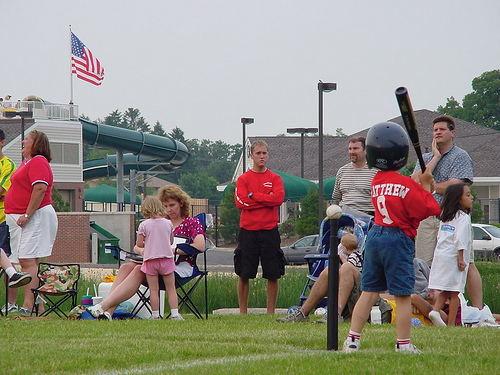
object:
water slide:
[80, 119, 189, 179]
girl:
[135, 195, 186, 320]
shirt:
[135, 217, 176, 261]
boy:
[232, 139, 286, 317]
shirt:
[232, 169, 286, 230]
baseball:
[325, 202, 342, 221]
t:
[327, 218, 340, 352]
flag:
[68, 30, 106, 87]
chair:
[32, 259, 82, 316]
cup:
[78, 295, 91, 319]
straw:
[85, 284, 90, 295]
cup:
[91, 294, 102, 306]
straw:
[92, 281, 98, 295]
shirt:
[370, 168, 442, 239]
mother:
[85, 182, 209, 318]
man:
[234, 137, 286, 318]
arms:
[234, 174, 264, 210]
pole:
[316, 89, 324, 228]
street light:
[315, 80, 340, 94]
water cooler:
[77, 278, 167, 321]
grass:
[1, 312, 499, 374]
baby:
[335, 232, 365, 274]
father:
[273, 262, 457, 326]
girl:
[425, 178, 476, 328]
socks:
[426, 307, 452, 329]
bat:
[392, 83, 436, 197]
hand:
[418, 166, 435, 184]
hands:
[247, 193, 254, 199]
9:
[375, 193, 395, 225]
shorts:
[141, 256, 177, 276]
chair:
[116, 213, 212, 320]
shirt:
[4, 154, 55, 216]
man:
[409, 114, 474, 277]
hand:
[429, 137, 443, 159]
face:
[432, 121, 450, 144]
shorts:
[232, 226, 288, 281]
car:
[471, 221, 499, 262]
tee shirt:
[425, 212, 472, 292]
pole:
[65, 20, 75, 118]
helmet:
[361, 119, 412, 170]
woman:
[6, 129, 63, 316]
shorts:
[3, 205, 61, 259]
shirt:
[428, 209, 474, 297]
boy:
[342, 122, 441, 356]